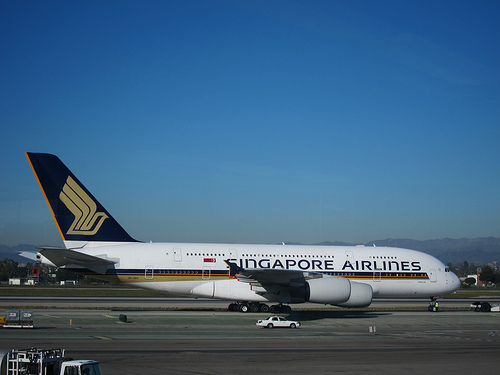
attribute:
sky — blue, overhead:
[2, 1, 500, 259]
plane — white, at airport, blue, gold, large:
[19, 151, 460, 315]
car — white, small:
[256, 317, 301, 330]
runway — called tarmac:
[2, 291, 500, 371]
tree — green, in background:
[476, 264, 499, 287]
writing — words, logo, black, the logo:
[223, 256, 423, 274]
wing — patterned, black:
[225, 262, 372, 308]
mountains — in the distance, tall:
[354, 235, 500, 270]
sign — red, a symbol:
[203, 256, 217, 263]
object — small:
[368, 327, 378, 335]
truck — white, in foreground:
[2, 346, 100, 375]